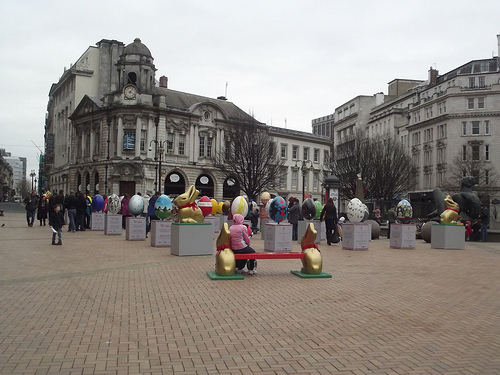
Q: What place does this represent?
A: It represents the sidewalk.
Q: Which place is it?
A: It is a sidewalk.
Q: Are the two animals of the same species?
A: Yes, all the animals are bunnies.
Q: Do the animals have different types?
A: No, all the animals are bunnies.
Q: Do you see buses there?
A: No, there are no buses.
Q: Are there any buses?
A: No, there are no buses.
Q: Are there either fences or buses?
A: No, there are no buses or fences.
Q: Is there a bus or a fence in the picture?
A: No, there are no buses or fences.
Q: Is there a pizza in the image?
A: No, there are no pizzas.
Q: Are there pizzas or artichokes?
A: No, there are no pizzas or artichokes.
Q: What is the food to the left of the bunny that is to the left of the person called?
A: The food is an egg.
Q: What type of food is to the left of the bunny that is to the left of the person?
A: The food is an egg.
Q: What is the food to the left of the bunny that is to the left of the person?
A: The food is an egg.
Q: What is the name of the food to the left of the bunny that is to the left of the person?
A: The food is an egg.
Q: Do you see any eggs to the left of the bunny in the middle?
A: Yes, there is an egg to the left of the bunny.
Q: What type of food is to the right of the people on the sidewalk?
A: The food is an egg.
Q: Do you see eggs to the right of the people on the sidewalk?
A: Yes, there is an egg to the right of the people.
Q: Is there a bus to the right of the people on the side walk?
A: No, there is an egg to the right of the people.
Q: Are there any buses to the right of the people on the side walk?
A: No, there is an egg to the right of the people.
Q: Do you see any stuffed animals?
A: No, there are no stuffed animals.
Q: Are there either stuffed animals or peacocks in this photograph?
A: No, there are no stuffed animals or peacocks.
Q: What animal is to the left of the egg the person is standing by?
A: The animal is a bunny.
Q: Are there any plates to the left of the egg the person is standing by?
A: No, there is a bunny to the left of the egg.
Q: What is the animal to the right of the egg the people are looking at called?
A: The animal is a bunny.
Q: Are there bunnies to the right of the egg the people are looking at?
A: Yes, there is a bunny to the right of the egg.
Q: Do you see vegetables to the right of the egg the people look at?
A: No, there is a bunny to the right of the egg.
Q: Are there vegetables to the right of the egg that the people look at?
A: No, there is a bunny to the right of the egg.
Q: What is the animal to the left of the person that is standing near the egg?
A: The animal is a bunny.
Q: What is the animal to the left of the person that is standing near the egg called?
A: The animal is a bunny.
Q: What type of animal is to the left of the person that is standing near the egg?
A: The animal is a bunny.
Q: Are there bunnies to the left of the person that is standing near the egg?
A: Yes, there is a bunny to the left of the person.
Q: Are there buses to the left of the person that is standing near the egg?
A: No, there is a bunny to the left of the person.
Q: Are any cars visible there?
A: No, there are no cars.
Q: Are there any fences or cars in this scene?
A: No, there are no cars or fences.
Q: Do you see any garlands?
A: No, there are no garlands.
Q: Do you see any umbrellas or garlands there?
A: No, there are no garlands or umbrellas.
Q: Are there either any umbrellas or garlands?
A: No, there are no garlands or umbrellas.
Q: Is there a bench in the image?
A: Yes, there is a bench.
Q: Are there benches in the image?
A: Yes, there is a bench.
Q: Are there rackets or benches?
A: Yes, there is a bench.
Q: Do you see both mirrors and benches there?
A: No, there is a bench but no mirrors.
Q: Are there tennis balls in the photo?
A: No, there are no tennis balls.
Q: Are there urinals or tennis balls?
A: No, there are no tennis balls or urinals.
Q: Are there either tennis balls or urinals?
A: No, there are no tennis balls or urinals.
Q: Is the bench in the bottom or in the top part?
A: The bench is in the bottom of the image.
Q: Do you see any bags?
A: No, there are no bags.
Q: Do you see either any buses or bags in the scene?
A: No, there are no bags or buses.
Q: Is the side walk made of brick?
A: Yes, the side walk is made of brick.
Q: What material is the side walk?
A: The side walk is made of brick.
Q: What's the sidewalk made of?
A: The side walk is made of brick.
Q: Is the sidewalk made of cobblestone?
A: No, the sidewalk is made of brick.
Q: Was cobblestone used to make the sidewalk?
A: No, the sidewalk is made of brick.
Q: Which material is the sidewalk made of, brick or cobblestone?
A: The sidewalk is made of brick.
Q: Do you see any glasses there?
A: No, there are no glasses.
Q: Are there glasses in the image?
A: No, there are no glasses.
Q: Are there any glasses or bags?
A: No, there are no glasses or bags.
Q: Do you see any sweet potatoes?
A: No, there are no sweet potatoes.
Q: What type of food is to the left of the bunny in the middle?
A: The food is an egg.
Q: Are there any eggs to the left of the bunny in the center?
A: Yes, there is an egg to the left of the bunny.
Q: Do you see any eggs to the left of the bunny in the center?
A: Yes, there is an egg to the left of the bunny.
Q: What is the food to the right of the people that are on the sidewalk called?
A: The food is an egg.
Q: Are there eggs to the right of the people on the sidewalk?
A: Yes, there is an egg to the right of the people.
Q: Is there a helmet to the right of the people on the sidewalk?
A: No, there is an egg to the right of the people.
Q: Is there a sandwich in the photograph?
A: No, there are no sandwiches.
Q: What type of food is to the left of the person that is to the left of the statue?
A: The food is an egg.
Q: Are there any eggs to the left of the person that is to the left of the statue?
A: Yes, there is an egg to the left of the person.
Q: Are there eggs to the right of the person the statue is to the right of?
A: No, the egg is to the left of the person.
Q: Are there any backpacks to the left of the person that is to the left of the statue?
A: No, there is an egg to the left of the person.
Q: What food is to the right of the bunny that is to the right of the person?
A: The food is an egg.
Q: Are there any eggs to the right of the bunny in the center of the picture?
A: Yes, there is an egg to the right of the bunny.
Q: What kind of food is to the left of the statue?
A: The food is an egg.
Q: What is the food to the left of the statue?
A: The food is an egg.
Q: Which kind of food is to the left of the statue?
A: The food is an egg.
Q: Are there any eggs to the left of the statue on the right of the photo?
A: Yes, there is an egg to the left of the statue.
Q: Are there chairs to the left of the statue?
A: No, there is an egg to the left of the statue.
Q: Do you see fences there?
A: No, there are no fences.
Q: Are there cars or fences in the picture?
A: No, there are no fences or cars.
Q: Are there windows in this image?
A: Yes, there is a window.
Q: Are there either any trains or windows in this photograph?
A: Yes, there is a window.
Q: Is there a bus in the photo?
A: No, there are no buses.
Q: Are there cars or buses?
A: No, there are no buses or cars.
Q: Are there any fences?
A: No, there are no fences.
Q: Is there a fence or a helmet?
A: No, there are no fences or helmets.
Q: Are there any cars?
A: No, there are no cars.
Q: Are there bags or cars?
A: No, there are no cars or bags.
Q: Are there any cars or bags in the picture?
A: No, there are no cars or bags.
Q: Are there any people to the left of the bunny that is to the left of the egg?
A: Yes, there is a person to the left of the bunny.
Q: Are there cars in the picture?
A: No, there are no cars.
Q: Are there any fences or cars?
A: No, there are no cars or fences.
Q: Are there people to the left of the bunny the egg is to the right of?
A: Yes, there is a person to the left of the bunny.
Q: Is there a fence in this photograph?
A: No, there are no fences.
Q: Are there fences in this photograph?
A: No, there are no fences.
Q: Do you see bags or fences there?
A: No, there are no fences or bags.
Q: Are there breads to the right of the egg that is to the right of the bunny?
A: No, there is a person to the right of the egg.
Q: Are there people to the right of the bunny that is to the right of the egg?
A: Yes, there is a person to the right of the bunny.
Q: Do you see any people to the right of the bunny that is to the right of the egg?
A: Yes, there is a person to the right of the bunny.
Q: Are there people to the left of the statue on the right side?
A: Yes, there is a person to the left of the statue.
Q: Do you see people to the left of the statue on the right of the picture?
A: Yes, there is a person to the left of the statue.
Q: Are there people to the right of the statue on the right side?
A: No, the person is to the left of the statue.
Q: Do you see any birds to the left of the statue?
A: No, there is a person to the left of the statue.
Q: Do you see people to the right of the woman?
A: Yes, there is a person to the right of the woman.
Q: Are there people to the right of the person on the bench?
A: Yes, there is a person to the right of the woman.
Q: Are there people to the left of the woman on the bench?
A: No, the person is to the right of the woman.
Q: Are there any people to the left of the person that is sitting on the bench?
A: No, the person is to the right of the woman.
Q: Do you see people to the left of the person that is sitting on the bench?
A: No, the person is to the right of the woman.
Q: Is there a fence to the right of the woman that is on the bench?
A: No, there is a person to the right of the woman.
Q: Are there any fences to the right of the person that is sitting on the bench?
A: No, there is a person to the right of the woman.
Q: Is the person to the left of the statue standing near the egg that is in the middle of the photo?
A: Yes, the person is standing near the egg.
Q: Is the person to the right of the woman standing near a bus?
A: No, the person is standing near the egg.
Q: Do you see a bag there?
A: No, there are no bags.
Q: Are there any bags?
A: No, there are no bags.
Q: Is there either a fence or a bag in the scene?
A: No, there are no bags or fences.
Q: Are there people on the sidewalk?
A: Yes, there are people on the sidewalk.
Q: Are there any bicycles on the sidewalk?
A: No, there are people on the sidewalk.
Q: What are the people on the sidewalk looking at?
A: The people are looking at the egg.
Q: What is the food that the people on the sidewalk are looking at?
A: The food is an egg.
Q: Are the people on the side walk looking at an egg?
A: Yes, the people are looking at an egg.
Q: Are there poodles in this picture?
A: No, there are no poodles.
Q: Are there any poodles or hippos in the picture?
A: No, there are no poodles or hippos.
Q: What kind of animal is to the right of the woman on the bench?
A: The animal is a bunny.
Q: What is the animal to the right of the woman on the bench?
A: The animal is a bunny.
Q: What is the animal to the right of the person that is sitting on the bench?
A: The animal is a bunny.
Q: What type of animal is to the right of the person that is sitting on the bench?
A: The animal is a bunny.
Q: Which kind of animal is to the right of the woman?
A: The animal is a bunny.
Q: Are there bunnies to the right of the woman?
A: Yes, there is a bunny to the right of the woman.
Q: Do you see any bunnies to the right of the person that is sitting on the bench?
A: Yes, there is a bunny to the right of the woman.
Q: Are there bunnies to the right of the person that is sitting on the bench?
A: Yes, there is a bunny to the right of the woman.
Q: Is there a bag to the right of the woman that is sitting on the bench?
A: No, there is a bunny to the right of the woman.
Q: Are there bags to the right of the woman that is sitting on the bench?
A: No, there is a bunny to the right of the woman.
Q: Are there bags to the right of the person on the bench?
A: No, there is a bunny to the right of the woman.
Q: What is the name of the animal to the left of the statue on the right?
A: The animal is a bunny.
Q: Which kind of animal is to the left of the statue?
A: The animal is a bunny.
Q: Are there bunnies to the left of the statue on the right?
A: Yes, there is a bunny to the left of the statue.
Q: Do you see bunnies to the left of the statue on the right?
A: Yes, there is a bunny to the left of the statue.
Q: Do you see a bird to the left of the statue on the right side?
A: No, there is a bunny to the left of the statue.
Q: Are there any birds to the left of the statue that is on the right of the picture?
A: No, there is a bunny to the left of the statue.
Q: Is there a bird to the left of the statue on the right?
A: No, there is a bunny to the left of the statue.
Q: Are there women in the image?
A: Yes, there is a woman.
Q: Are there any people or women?
A: Yes, there is a woman.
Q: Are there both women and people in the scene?
A: Yes, there are both a woman and a person.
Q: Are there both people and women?
A: Yes, there are both a woman and a person.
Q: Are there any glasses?
A: No, there are no glasses.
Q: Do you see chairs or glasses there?
A: No, there are no glasses or chairs.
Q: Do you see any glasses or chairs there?
A: No, there are no glasses or chairs.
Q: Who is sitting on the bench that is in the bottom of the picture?
A: The woman is sitting on the bench.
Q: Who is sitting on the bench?
A: The woman is sitting on the bench.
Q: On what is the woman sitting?
A: The woman is sitting on the bench.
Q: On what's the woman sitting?
A: The woman is sitting on the bench.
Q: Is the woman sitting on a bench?
A: Yes, the woman is sitting on a bench.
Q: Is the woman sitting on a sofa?
A: No, the woman is sitting on a bench.